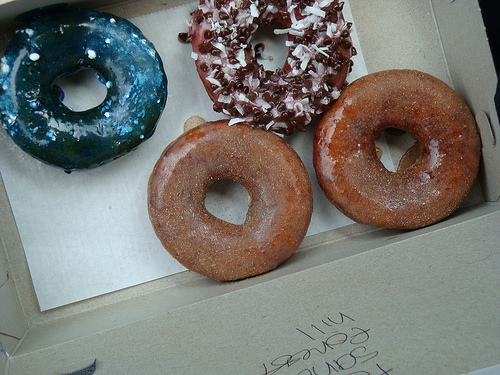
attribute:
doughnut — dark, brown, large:
[181, 0, 357, 140]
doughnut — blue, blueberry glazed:
[0, 11, 167, 174]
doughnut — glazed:
[149, 118, 314, 281]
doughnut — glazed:
[316, 65, 479, 230]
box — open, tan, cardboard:
[0, 0, 499, 373]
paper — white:
[0, 0, 398, 311]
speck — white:
[314, 45, 328, 56]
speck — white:
[294, 101, 305, 113]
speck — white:
[207, 74, 220, 90]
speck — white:
[214, 37, 228, 54]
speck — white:
[250, 3, 262, 21]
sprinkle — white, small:
[28, 50, 41, 64]